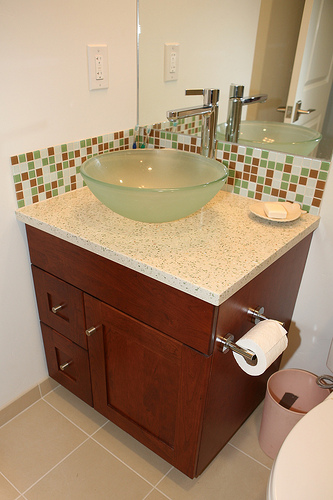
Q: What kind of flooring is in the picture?
A: Beige tiled.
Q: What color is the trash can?
A: Peach.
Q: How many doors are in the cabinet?
A: One.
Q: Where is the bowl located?
A: On top of the counter.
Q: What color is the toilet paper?
A: White.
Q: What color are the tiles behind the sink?
A: Red, green and white.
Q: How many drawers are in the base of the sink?
A: Two.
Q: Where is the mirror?
A: Behind the sink.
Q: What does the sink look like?
A: A bowl.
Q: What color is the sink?
A: Green.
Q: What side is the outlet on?
A: Left.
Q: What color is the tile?
A: Green. Brown. White.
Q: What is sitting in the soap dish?
A: Bar of soap.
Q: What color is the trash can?
A: Pink.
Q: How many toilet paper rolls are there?
A: One.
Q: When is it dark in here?
A: When the lights are off.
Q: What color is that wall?
A: White.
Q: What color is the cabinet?
A: Brown.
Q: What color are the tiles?
A: Green, brown, white.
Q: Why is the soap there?
A: To wash your hands.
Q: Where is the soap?
A: On the dish.